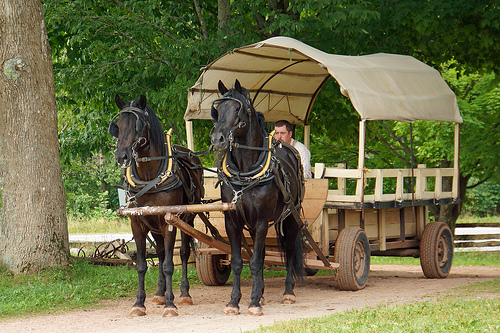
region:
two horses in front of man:
[55, 87, 300, 264]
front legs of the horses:
[209, 216, 282, 314]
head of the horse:
[188, 75, 267, 167]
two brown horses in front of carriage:
[48, 80, 302, 259]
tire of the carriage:
[321, 213, 390, 300]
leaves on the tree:
[76, 33, 187, 101]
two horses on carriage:
[124, 73, 379, 316]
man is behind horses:
[236, 116, 318, 162]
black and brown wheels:
[297, 204, 384, 316]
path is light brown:
[340, 268, 426, 327]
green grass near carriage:
[332, 298, 447, 330]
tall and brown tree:
[0, 21, 57, 276]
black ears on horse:
[111, 88, 164, 132]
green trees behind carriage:
[119, 9, 179, 94]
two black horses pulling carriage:
[108, 84, 310, 317]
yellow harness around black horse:
[221, 123, 278, 192]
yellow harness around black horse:
[122, 121, 180, 190]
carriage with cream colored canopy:
[181, 33, 468, 285]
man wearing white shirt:
[266, 140, 313, 175]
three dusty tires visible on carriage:
[192, 218, 459, 293]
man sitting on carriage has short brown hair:
[272, 117, 292, 138]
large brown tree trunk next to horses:
[1, 1, 72, 268]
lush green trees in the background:
[43, 0, 497, 216]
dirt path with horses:
[17, 258, 494, 332]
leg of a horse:
[242, 228, 278, 318]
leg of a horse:
[216, 221, 242, 314]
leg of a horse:
[150, 225, 185, 325]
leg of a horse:
[121, 230, 148, 321]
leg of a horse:
[176, 238, 196, 308]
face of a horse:
[105, 90, 145, 177]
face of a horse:
[205, 75, 250, 160]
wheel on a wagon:
[328, 225, 383, 293]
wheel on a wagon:
[415, 220, 461, 273]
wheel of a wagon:
[192, 249, 227, 286]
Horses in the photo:
[101, 81, 313, 298]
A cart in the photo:
[274, 126, 456, 296]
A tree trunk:
[0, 19, 80, 276]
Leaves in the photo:
[100, 0, 237, 63]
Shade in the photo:
[207, 45, 457, 145]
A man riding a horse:
[258, 104, 323, 193]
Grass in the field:
[363, 295, 485, 328]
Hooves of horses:
[114, 256, 295, 313]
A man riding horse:
[269, 117, 316, 185]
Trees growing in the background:
[85, 14, 208, 72]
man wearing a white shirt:
[286, 140, 315, 182]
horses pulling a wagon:
[91, 68, 308, 287]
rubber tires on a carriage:
[333, 221, 375, 288]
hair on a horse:
[138, 100, 170, 164]